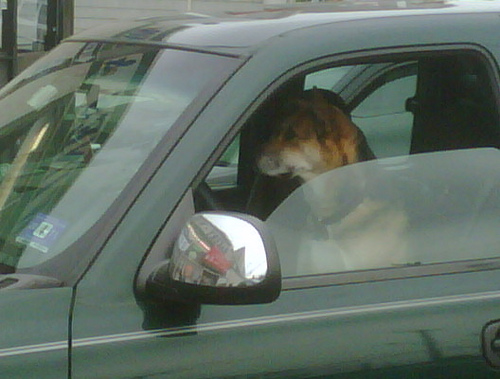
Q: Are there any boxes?
A: No, there are no boxes.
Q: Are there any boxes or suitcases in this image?
A: No, there are no boxes or suitcases.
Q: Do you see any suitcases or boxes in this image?
A: No, there are no boxes or suitcases.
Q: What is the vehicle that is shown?
A: The vehicle is a car.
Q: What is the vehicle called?
A: The vehicle is a car.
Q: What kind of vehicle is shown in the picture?
A: The vehicle is a car.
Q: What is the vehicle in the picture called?
A: The vehicle is a car.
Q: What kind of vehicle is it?
A: The vehicle is a car.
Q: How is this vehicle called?
A: This is a car.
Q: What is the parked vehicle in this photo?
A: The vehicle is a car.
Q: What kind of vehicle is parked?
A: The vehicle is a car.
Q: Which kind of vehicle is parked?
A: The vehicle is a car.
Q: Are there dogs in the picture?
A: Yes, there is a dog.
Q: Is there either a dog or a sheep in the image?
A: Yes, there is a dog.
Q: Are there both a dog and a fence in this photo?
A: No, there is a dog but no fences.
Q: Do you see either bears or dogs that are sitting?
A: Yes, the dog is sitting.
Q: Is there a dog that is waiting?
A: Yes, there is a dog that is waiting.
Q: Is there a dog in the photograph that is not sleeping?
A: Yes, there is a dog that is waiting.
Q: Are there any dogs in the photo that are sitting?
A: Yes, there is a dog that is sitting.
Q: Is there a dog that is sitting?
A: Yes, there is a dog that is sitting.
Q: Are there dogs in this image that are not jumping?
A: Yes, there is a dog that is sitting.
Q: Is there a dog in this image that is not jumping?
A: Yes, there is a dog that is sitting.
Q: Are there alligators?
A: No, there are no alligators.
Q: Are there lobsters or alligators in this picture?
A: No, there are no alligators or lobsters.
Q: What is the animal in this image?
A: The animal is a dog.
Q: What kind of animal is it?
A: The animal is a dog.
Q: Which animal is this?
A: This is a dog.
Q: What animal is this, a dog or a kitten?
A: This is a dog.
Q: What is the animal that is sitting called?
A: The animal is a dog.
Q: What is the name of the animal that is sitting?
A: The animal is a dog.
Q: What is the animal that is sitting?
A: The animal is a dog.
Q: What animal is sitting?
A: The animal is a dog.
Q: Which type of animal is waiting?
A: The animal is a dog.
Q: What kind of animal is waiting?
A: The animal is a dog.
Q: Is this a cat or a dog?
A: This is a dog.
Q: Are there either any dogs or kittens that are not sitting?
A: No, there is a dog but it is sitting.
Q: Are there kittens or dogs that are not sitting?
A: No, there is a dog but it is sitting.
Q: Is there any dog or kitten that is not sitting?
A: No, there is a dog but it is sitting.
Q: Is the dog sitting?
A: Yes, the dog is sitting.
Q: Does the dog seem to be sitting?
A: Yes, the dog is sitting.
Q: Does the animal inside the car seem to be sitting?
A: Yes, the dog is sitting.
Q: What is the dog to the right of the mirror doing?
A: The dog is sitting.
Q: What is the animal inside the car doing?
A: The dog is sitting.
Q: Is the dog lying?
A: No, the dog is sitting.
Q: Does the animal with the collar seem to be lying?
A: No, the dog is sitting.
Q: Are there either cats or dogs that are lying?
A: No, there is a dog but it is sitting.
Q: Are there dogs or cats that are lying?
A: No, there is a dog but it is sitting.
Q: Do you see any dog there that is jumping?
A: No, there is a dog but it is sitting.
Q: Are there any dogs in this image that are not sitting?
A: No, there is a dog but it is sitting.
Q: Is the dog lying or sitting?
A: The dog is sitting.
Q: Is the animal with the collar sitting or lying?
A: The dog is sitting.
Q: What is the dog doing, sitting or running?
A: The dog is sitting.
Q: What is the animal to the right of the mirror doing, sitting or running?
A: The dog is sitting.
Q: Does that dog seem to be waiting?
A: Yes, the dog is waiting.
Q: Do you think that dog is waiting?
A: Yes, the dog is waiting.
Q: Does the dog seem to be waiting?
A: Yes, the dog is waiting.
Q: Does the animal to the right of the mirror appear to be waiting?
A: Yes, the dog is waiting.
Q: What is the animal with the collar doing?
A: The dog is waiting.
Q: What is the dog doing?
A: The dog is waiting.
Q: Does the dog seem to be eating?
A: No, the dog is waiting.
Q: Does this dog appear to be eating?
A: No, the dog is waiting.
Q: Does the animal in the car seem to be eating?
A: No, the dog is waiting.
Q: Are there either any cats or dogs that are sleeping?
A: No, there is a dog but it is waiting.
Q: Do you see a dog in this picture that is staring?
A: No, there is a dog but it is waiting.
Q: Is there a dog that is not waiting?
A: No, there is a dog but it is waiting.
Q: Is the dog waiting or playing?
A: The dog is waiting.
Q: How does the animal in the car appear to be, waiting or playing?
A: The dog is waiting.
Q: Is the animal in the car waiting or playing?
A: The dog is waiting.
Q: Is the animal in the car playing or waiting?
A: The dog is waiting.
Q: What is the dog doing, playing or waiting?
A: The dog is waiting.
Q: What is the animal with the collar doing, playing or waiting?
A: The dog is waiting.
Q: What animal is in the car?
A: The dog is in the car.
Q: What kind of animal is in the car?
A: The animal is a dog.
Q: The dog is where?
A: The dog is in the car.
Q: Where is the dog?
A: The dog is in the car.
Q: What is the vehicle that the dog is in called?
A: The vehicle is a car.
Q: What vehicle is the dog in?
A: The dog is in the car.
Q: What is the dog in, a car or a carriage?
A: The dog is in a car.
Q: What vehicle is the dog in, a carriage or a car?
A: The dog is in a car.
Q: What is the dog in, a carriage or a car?
A: The dog is in a car.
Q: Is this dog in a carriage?
A: No, the dog is in the car.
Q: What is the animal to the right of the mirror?
A: The animal is a dog.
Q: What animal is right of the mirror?
A: The animal is a dog.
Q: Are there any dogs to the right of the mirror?
A: Yes, there is a dog to the right of the mirror.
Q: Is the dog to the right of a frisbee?
A: No, the dog is to the right of a mirror.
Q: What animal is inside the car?
A: The dog is inside the car.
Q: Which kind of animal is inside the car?
A: The animal is a dog.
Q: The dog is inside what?
A: The dog is inside the car.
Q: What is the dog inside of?
A: The dog is inside the car.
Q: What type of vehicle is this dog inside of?
A: The dog is inside the car.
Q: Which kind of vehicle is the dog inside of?
A: The dog is inside the car.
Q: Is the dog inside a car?
A: Yes, the dog is inside a car.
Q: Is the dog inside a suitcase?
A: No, the dog is inside a car.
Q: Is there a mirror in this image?
A: Yes, there is a mirror.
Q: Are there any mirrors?
A: Yes, there is a mirror.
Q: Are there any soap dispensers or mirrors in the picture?
A: Yes, there is a mirror.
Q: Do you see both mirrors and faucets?
A: No, there is a mirror but no faucets.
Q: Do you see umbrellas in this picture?
A: No, there are no umbrellas.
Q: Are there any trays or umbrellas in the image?
A: No, there are no umbrellas or trays.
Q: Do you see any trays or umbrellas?
A: No, there are no umbrellas or trays.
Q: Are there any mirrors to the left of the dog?
A: Yes, there is a mirror to the left of the dog.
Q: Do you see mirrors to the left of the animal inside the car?
A: Yes, there is a mirror to the left of the dog.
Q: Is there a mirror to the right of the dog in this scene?
A: No, the mirror is to the left of the dog.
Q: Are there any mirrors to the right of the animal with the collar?
A: No, the mirror is to the left of the dog.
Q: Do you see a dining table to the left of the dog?
A: No, there is a mirror to the left of the dog.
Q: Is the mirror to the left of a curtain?
A: No, the mirror is to the left of the dog.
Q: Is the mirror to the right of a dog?
A: No, the mirror is to the left of a dog.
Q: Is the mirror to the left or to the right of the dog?
A: The mirror is to the left of the dog.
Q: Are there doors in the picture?
A: Yes, there is a door.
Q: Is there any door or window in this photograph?
A: Yes, there is a door.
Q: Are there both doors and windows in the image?
A: Yes, there are both a door and a window.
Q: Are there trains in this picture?
A: No, there are no trains.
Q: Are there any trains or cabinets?
A: No, there are no trains or cabinets.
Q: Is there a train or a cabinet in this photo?
A: No, there are no trains or cabinets.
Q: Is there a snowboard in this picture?
A: No, there are no snowboards.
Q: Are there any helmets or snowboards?
A: No, there are no snowboards or helmets.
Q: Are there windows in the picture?
A: Yes, there is a window.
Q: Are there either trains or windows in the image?
A: Yes, there is a window.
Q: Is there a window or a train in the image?
A: Yes, there is a window.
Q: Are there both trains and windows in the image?
A: No, there is a window but no trains.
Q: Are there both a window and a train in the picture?
A: No, there is a window but no trains.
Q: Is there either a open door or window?
A: Yes, there is an open window.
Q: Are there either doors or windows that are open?
A: Yes, the window is open.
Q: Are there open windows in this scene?
A: Yes, there is an open window.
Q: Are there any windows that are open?
A: Yes, there is a window that is open.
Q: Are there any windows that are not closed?
A: Yes, there is a open window.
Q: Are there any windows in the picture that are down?
A: Yes, there is a window that is down.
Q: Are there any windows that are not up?
A: Yes, there is a window that is down.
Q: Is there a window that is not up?
A: Yes, there is a window that is down.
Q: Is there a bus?
A: No, there are no buses.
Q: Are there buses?
A: No, there are no buses.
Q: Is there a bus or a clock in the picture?
A: No, there are no buses or clocks.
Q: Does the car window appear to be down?
A: Yes, the window is down.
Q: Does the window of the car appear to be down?
A: Yes, the window is down.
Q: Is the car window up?
A: No, the window is down.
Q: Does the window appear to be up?
A: No, the window is down.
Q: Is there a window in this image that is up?
A: No, there is a window but it is down.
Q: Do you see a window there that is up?
A: No, there is a window but it is down.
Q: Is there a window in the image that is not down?
A: No, there is a window but it is down.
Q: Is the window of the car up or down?
A: The window is down.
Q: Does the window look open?
A: Yes, the window is open.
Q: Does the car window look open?
A: Yes, the window is open.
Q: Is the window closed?
A: No, the window is open.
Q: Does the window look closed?
A: No, the window is open.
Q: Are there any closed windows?
A: No, there is a window but it is open.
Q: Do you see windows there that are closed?
A: No, there is a window but it is open.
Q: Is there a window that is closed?
A: No, there is a window but it is open.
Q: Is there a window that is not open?
A: No, there is a window but it is open.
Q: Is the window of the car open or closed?
A: The window is open.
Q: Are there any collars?
A: Yes, there is a collar.